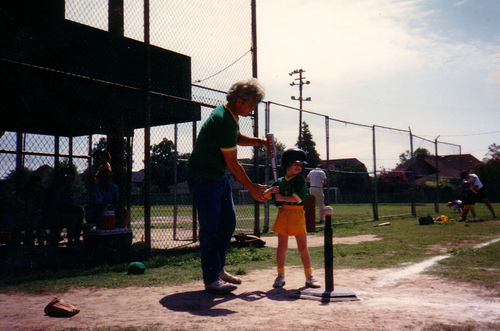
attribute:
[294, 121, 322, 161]
tree — distance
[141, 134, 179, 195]
tree — distance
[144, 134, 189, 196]
tree — distance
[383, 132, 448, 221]
tree — distance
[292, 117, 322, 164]
tree — distance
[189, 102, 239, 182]
shirt — green, yellow, ringer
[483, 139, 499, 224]
tree — distance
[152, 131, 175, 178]
tree — distance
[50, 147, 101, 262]
tree — distance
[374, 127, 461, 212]
tree — distance